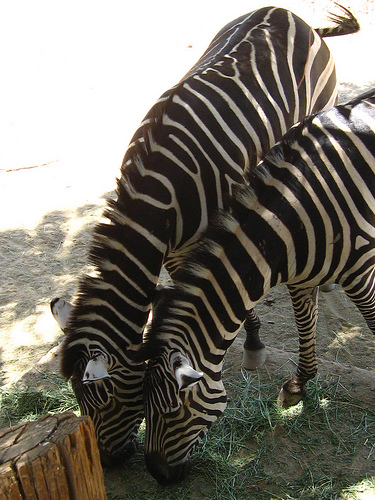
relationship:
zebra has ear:
[51, 3, 365, 469] [82, 354, 113, 385]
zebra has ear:
[51, 3, 365, 469] [49, 295, 76, 332]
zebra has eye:
[51, 3, 375, 469] [163, 405, 182, 419]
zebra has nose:
[51, 3, 375, 469] [146, 449, 169, 482]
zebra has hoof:
[51, 3, 365, 469] [240, 348, 269, 371]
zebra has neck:
[51, 3, 365, 469] [74, 182, 170, 344]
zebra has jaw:
[51, 3, 375, 469] [189, 377, 232, 461]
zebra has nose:
[51, 3, 365, 469] [99, 445, 115, 470]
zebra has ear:
[51, 3, 375, 469] [175, 365, 209, 389]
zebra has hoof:
[51, 3, 375, 469] [277, 381, 304, 409]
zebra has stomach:
[51, 3, 375, 469] [287, 261, 353, 292]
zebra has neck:
[51, 3, 375, 469] [154, 263, 269, 365]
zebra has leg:
[51, 3, 375, 469] [276, 283, 321, 411]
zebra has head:
[51, 3, 365, 469] [47, 291, 146, 468]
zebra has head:
[51, 3, 375, 469] [127, 333, 232, 485]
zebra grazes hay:
[51, 3, 365, 469] [2, 370, 374, 496]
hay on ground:
[2, 370, 374, 496] [1, 164, 370, 499]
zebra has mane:
[51, 3, 365, 469] [65, 178, 125, 375]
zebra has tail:
[51, 3, 365, 469] [311, 1, 364, 40]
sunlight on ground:
[1, 296, 63, 393] [1, 164, 370, 499]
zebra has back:
[51, 3, 365, 469] [117, 7, 304, 178]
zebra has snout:
[51, 3, 375, 469] [146, 443, 193, 486]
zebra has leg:
[51, 3, 375, 469] [339, 274, 374, 332]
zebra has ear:
[51, 3, 375, 469] [123, 340, 168, 365]